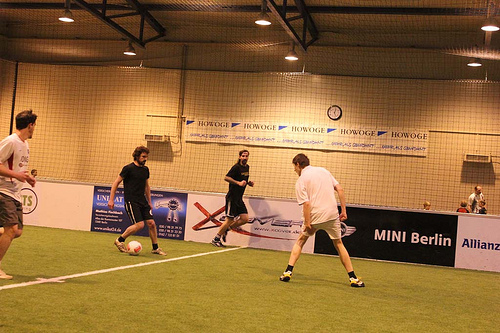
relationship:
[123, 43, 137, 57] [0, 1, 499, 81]
light hanging on roof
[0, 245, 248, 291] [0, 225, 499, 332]
line on top of court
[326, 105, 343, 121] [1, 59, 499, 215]
clock hanging on wall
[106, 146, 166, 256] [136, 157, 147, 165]
person has beard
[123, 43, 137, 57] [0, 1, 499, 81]
light suspended from roof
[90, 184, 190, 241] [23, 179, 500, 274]
advertisement on front of wall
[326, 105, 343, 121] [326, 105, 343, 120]
clock has frame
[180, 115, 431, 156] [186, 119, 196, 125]
banner with triangle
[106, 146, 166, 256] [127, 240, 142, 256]
person next to ball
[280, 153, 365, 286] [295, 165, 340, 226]
person wearing shirt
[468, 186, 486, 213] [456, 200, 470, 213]
adult next to child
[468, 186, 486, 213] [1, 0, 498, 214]
adult behind net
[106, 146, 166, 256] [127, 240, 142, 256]
person kicking ball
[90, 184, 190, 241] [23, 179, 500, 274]
advertisement on edge of wall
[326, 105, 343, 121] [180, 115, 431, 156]
clock above banner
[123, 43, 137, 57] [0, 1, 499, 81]
light hanging from roof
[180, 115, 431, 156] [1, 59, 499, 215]
banner hanging on wall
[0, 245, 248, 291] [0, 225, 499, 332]
line across court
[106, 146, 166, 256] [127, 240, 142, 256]
person taking ball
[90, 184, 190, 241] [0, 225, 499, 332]
advertisement next to court